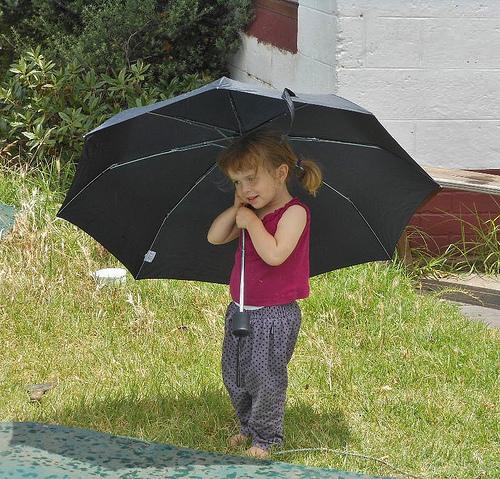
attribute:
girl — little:
[205, 125, 317, 415]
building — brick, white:
[225, 1, 498, 263]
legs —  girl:
[217, 336, 296, 438]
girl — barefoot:
[198, 124, 328, 464]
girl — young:
[213, 101, 363, 459]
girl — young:
[210, 144, 317, 473]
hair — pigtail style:
[215, 130, 350, 190]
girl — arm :
[202, 135, 340, 468]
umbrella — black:
[10, 35, 447, 272]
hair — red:
[219, 130, 320, 197]